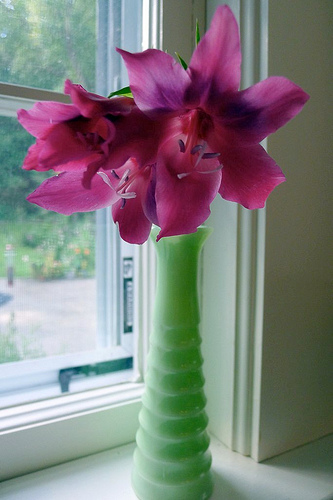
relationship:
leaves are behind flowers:
[173, 17, 199, 70] [15, 5, 311, 241]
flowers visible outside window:
[28, 233, 89, 274] [0, 0, 155, 411]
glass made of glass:
[129, 225, 212, 500] [133, 225, 231, 498]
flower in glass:
[119, 6, 309, 224] [129, 225, 212, 500]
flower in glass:
[18, 80, 142, 193] [129, 225, 212, 500]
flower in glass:
[27, 140, 164, 246] [129, 225, 212, 500]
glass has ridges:
[129, 225, 212, 500] [122, 320, 234, 498]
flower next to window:
[115, 4, 309, 244] [7, 5, 186, 477]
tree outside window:
[0, 0, 97, 275] [0, 0, 160, 484]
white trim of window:
[138, 1, 207, 65] [1, 2, 138, 405]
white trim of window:
[1, 384, 146, 481] [1, 2, 138, 405]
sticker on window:
[123, 257, 134, 335] [7, 5, 186, 477]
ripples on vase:
[118, 316, 228, 498] [127, 286, 225, 498]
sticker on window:
[120, 257, 134, 335] [0, 2, 203, 479]